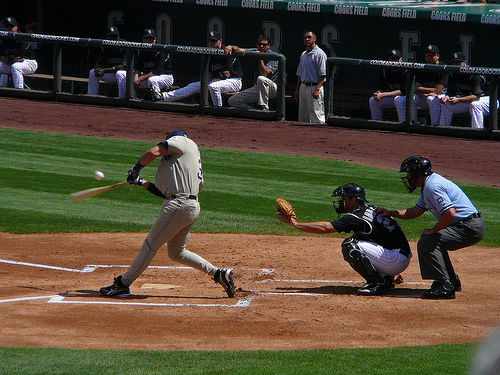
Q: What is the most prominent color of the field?
A: Green.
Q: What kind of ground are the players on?
A: Dirt.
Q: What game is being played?
A: Baseball.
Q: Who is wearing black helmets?
A: Two baseball players.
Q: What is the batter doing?
A: Hitting the ball.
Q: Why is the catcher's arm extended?
A: To catch the ball.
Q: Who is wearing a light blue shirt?
A: The player behind the catcher.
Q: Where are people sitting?
A: At the edge of the field.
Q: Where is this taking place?
A: On a baseball field.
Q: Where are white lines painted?
A: On the field.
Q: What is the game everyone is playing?
A: Baseball.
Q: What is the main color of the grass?
A: Green.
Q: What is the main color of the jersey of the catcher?
A: Green.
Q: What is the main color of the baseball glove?
A: Brown.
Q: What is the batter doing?
A: Swinging a bat.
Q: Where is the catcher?
A: Behind home plate.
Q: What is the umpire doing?
A: Watching a play.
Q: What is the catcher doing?
A: Kneeling down.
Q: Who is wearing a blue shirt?
A: Umpire.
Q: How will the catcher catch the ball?
A: In baseball glove.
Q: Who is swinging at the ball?
A: Batter.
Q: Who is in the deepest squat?
A: Catcher.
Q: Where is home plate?
A: In front of batter.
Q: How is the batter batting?
A: Right handed.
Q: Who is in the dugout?
A: Catcher's teammates.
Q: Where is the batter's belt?
A: In his belt loops.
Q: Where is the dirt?
A: Inside of grass.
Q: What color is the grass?
A: Green.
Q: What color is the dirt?
A: Brown.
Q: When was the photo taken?
A: Daytime.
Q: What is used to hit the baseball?
A: A bat.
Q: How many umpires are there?
A: One.